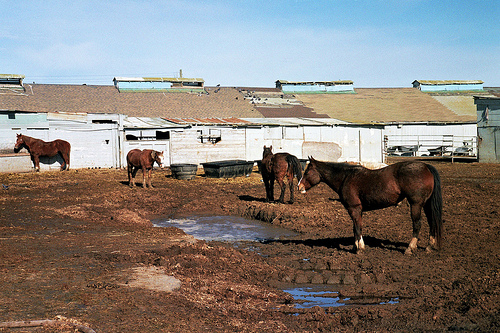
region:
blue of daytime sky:
[0, 0, 498, 86]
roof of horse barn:
[0, 84, 458, 169]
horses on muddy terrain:
[2, 130, 495, 330]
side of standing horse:
[298, 156, 445, 253]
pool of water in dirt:
[149, 208, 302, 243]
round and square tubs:
[168, 157, 252, 179]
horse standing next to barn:
[14, 130, 72, 170]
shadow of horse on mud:
[268, 232, 428, 254]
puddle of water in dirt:
[279, 277, 414, 316]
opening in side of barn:
[122, 128, 169, 165]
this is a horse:
[291, 148, 441, 271]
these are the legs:
[400, 206, 428, 246]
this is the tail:
[427, 186, 447, 221]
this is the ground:
[20, 200, 107, 287]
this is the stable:
[340, 89, 408, 144]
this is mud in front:
[207, 208, 255, 237]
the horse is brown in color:
[370, 166, 394, 187]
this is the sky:
[213, 10, 287, 60]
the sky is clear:
[275, 8, 332, 60]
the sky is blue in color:
[375, 8, 437, 55]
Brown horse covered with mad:
[297, 157, 449, 256]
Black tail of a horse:
[430, 163, 448, 247]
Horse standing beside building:
[14, 135, 72, 170]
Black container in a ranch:
[202, 158, 255, 175]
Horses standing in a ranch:
[12, 131, 451, 258]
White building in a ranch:
[0, 73, 499, 170]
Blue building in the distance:
[414, 77, 484, 94]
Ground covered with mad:
[0, 166, 497, 331]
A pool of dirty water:
[154, 209, 296, 244]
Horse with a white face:
[156, 150, 166, 170]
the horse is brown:
[289, 159, 463, 258]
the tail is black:
[423, 187, 455, 227]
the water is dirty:
[159, 204, 311, 259]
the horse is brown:
[15, 130, 96, 171]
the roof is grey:
[161, 86, 253, 129]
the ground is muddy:
[3, 125, 495, 332]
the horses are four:
[11, 124, 455, 269]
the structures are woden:
[1, 79, 496, 181]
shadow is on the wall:
[38, 157, 65, 169]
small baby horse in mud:
[292, 143, 447, 257]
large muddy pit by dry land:
[130, 193, 300, 285]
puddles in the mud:
[247, 262, 414, 316]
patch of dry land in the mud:
[94, 231, 205, 318]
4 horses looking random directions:
[8, 43, 450, 276]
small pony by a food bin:
[116, 128, 241, 190]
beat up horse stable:
[127, 60, 479, 152]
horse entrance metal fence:
[370, 122, 490, 156]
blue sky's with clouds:
[57, 0, 415, 64]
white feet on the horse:
[337, 223, 443, 262]